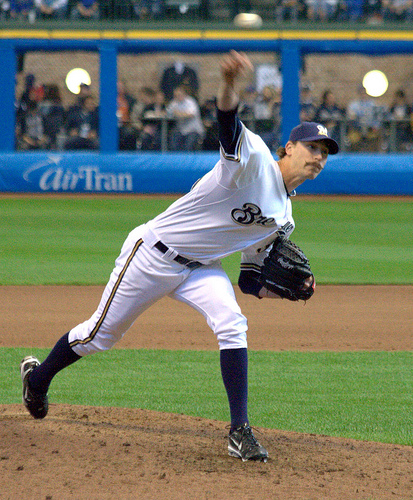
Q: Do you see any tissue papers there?
A: No, there are no tissue papers.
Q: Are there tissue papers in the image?
A: No, there are no tissue papers.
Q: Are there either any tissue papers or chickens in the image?
A: No, there are no tissue papers or chickens.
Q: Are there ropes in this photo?
A: No, there are no ropes.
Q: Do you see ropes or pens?
A: No, there are no ropes or pens.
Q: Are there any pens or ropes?
A: No, there are no ropes or pens.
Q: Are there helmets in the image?
A: No, there are no helmets.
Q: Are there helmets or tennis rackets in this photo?
A: No, there are no helmets or tennis rackets.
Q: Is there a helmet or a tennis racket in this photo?
A: No, there are no helmets or rackets.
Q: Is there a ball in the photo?
A: Yes, there is a ball.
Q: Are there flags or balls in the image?
A: Yes, there is a ball.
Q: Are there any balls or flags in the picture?
A: Yes, there is a ball.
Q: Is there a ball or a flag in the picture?
A: Yes, there is a ball.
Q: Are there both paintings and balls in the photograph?
A: No, there is a ball but no paintings.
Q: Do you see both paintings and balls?
A: No, there is a ball but no paintings.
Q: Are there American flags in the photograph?
A: No, there are no American flags.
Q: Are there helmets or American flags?
A: No, there are no American flags or helmets.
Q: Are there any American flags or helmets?
A: No, there are no American flags or helmets.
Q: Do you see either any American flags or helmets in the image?
A: No, there are no American flags or helmets.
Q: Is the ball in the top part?
A: Yes, the ball is in the top of the image.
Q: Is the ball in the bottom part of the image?
A: No, the ball is in the top of the image.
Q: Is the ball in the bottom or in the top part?
A: The ball is in the top of the image.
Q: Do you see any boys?
A: No, there are no boys.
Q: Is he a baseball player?
A: Yes, that is a baseball player.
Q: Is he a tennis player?
A: No, that is a baseball player.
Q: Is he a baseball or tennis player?
A: That is a baseball player.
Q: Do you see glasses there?
A: No, there are no glasses.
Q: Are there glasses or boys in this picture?
A: No, there are no glasses or boys.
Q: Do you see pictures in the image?
A: No, there are no pictures.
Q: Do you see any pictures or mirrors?
A: No, there are no pictures or mirrors.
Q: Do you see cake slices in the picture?
A: No, there are no cake slices.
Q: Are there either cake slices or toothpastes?
A: No, there are no cake slices or toothpastes.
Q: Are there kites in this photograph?
A: No, there are no kites.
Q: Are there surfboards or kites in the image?
A: No, there are no kites or surfboards.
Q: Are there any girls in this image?
A: No, there are no girls.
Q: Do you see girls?
A: No, there are no girls.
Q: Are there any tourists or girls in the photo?
A: No, there are no girls or tourists.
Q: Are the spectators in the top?
A: Yes, the spectators are in the top of the image.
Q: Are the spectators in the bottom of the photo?
A: No, the spectators are in the top of the image.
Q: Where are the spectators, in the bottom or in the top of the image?
A: The spectators are in the top of the image.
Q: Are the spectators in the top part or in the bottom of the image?
A: The spectators are in the top of the image.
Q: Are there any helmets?
A: No, there are no helmets.